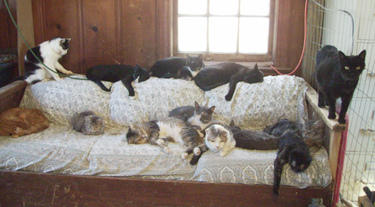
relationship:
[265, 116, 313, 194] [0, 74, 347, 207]
cat lying on couch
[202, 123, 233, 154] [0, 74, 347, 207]
cat lying on couch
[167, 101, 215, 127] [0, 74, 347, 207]
cat lying on couch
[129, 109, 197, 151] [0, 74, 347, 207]
cat lying on couch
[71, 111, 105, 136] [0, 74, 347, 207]
cat lying on couch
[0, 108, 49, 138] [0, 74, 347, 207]
brown cat lying on couch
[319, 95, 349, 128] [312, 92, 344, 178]
cat on arm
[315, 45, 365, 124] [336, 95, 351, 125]
cat on arm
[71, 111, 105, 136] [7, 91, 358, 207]
cat on bed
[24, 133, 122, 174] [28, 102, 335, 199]
mattress on bed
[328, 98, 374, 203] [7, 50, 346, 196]
cage next to couch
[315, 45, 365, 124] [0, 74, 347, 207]
cat on couch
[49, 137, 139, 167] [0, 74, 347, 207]
material covering couch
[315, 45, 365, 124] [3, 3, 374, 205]
cat infestation in room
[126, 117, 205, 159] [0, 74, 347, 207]
cat laying on couch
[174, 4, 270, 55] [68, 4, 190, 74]
window on wall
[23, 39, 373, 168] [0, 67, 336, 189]
cats on couch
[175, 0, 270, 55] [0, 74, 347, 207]
window behind couch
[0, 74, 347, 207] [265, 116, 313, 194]
couch of cat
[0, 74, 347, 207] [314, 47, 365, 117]
couch of cat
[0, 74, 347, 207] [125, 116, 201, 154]
couch of cat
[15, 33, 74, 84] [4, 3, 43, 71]
cat pawing cord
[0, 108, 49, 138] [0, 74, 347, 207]
brown cat curled up on couch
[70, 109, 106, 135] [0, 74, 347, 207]
cat on couch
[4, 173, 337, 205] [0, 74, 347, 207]
panel on bottom of couch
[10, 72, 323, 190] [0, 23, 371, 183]
couch covered in cats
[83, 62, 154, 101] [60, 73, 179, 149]
cat on cushion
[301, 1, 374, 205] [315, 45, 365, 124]
fence for cat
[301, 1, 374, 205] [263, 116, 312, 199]
fence for cat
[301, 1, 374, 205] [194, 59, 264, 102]
fence for cat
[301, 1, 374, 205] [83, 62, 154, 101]
fence for cat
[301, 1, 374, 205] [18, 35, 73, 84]
fence for cat